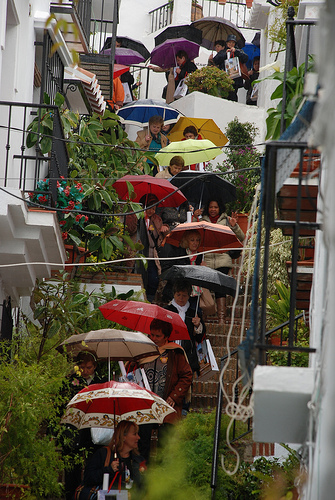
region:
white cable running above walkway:
[3, 247, 238, 270]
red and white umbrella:
[68, 379, 175, 426]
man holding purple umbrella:
[152, 41, 200, 62]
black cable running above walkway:
[2, 118, 264, 158]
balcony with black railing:
[1, 100, 67, 295]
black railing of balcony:
[1, 102, 66, 210]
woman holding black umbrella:
[167, 261, 229, 309]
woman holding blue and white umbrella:
[114, 96, 172, 139]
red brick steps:
[195, 380, 215, 400]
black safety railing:
[144, 0, 175, 29]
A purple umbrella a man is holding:
[148, 37, 200, 69]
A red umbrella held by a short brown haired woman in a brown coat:
[97, 296, 191, 342]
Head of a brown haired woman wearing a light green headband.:
[74, 349, 98, 380]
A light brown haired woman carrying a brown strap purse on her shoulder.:
[83, 417, 147, 497]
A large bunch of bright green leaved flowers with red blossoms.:
[30, 178, 88, 243]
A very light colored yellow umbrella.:
[152, 139, 221, 165]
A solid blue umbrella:
[237, 38, 261, 69]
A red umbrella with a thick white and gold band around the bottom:
[60, 381, 176, 430]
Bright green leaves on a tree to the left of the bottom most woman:
[3, 336, 75, 498]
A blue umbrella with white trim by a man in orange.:
[116, 96, 182, 125]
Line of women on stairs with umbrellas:
[82, 29, 257, 493]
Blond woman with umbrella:
[57, 381, 187, 468]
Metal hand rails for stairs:
[230, 168, 264, 442]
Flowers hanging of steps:
[32, 157, 99, 267]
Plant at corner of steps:
[176, 59, 235, 107]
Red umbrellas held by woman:
[87, 282, 197, 346]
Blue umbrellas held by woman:
[112, 91, 181, 129]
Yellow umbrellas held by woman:
[149, 136, 219, 172]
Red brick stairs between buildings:
[208, 316, 247, 420]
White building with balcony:
[253, 38, 319, 489]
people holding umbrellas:
[40, 5, 294, 486]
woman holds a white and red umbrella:
[54, 376, 180, 498]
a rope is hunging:
[219, 178, 262, 478]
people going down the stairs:
[44, 5, 273, 494]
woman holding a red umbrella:
[99, 288, 188, 345]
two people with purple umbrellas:
[103, 36, 195, 91]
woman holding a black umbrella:
[157, 253, 238, 320]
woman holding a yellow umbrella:
[158, 113, 235, 145]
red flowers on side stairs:
[21, 164, 110, 270]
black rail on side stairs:
[4, 96, 79, 190]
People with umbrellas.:
[128, 107, 237, 312]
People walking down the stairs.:
[117, 171, 222, 411]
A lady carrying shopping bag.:
[186, 311, 226, 387]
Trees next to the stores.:
[16, 290, 72, 471]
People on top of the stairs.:
[160, 15, 251, 95]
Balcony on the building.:
[12, 100, 81, 261]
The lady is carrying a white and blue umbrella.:
[124, 101, 183, 134]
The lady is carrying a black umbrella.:
[163, 257, 232, 311]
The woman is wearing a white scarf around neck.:
[169, 296, 199, 320]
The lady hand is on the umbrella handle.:
[101, 439, 128, 473]